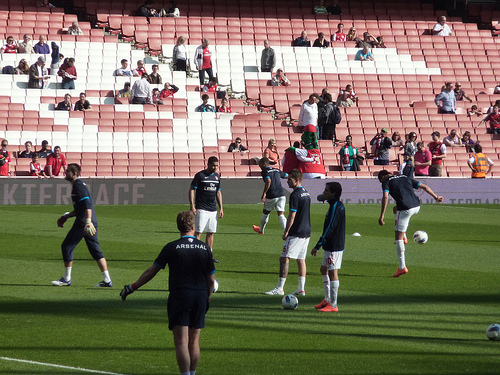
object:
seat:
[400, 60, 413, 68]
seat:
[426, 60, 440, 68]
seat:
[398, 48, 410, 55]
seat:
[426, 61, 439, 68]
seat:
[425, 54, 438, 61]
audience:
[339, 134, 365, 171]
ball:
[485, 323, 500, 342]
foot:
[393, 238, 407, 245]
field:
[0, 0, 500, 375]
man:
[188, 156, 223, 264]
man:
[227, 137, 250, 155]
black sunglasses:
[235, 141, 241, 144]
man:
[50, 163, 114, 289]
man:
[310, 181, 346, 313]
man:
[377, 170, 443, 278]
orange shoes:
[317, 302, 338, 312]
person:
[453, 81, 473, 103]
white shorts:
[321, 250, 344, 271]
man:
[264, 168, 312, 296]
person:
[194, 37, 215, 85]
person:
[172, 35, 188, 71]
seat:
[216, 72, 231, 85]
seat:
[216, 58, 230, 66]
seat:
[216, 32, 228, 40]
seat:
[189, 30, 202, 40]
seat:
[172, 71, 186, 80]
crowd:
[291, 22, 387, 61]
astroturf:
[0, 203, 500, 375]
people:
[280, 141, 320, 174]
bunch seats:
[0, 0, 500, 179]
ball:
[281, 294, 298, 311]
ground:
[0, 203, 500, 375]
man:
[261, 39, 277, 72]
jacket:
[261, 46, 277, 71]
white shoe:
[264, 286, 285, 295]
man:
[120, 211, 217, 374]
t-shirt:
[67, 178, 99, 228]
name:
[176, 243, 208, 250]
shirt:
[152, 235, 216, 294]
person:
[467, 144, 494, 180]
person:
[426, 131, 447, 177]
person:
[414, 142, 433, 177]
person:
[404, 132, 418, 167]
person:
[391, 131, 406, 148]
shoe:
[314, 298, 330, 309]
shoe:
[290, 290, 306, 296]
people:
[54, 93, 72, 111]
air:
[0, 0, 500, 375]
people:
[298, 94, 320, 141]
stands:
[231, 116, 388, 177]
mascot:
[434, 82, 457, 114]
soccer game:
[0, 155, 500, 372]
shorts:
[279, 235, 310, 260]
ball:
[413, 229, 429, 245]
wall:
[0, 174, 500, 205]